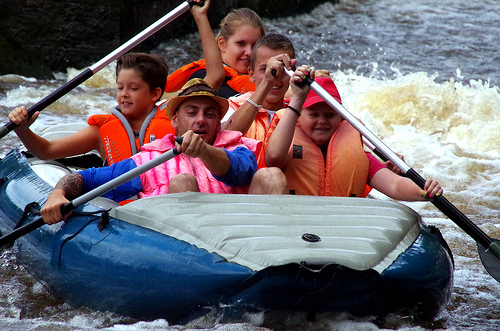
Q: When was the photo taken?
A: Daytime.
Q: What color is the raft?
A: Blue and gray.